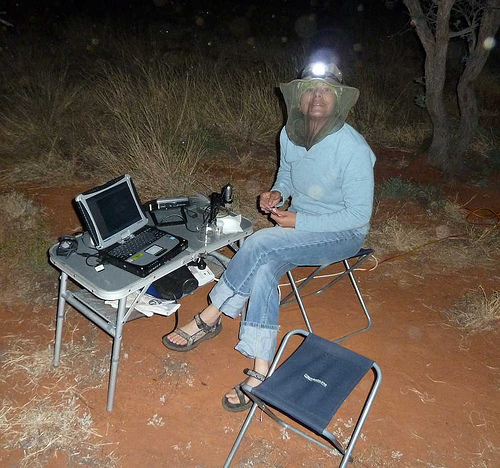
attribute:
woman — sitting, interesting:
[160, 47, 386, 418]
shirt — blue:
[250, 120, 384, 242]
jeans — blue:
[189, 217, 367, 353]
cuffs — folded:
[207, 272, 286, 356]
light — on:
[308, 62, 329, 79]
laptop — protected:
[69, 174, 182, 276]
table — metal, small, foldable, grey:
[45, 189, 254, 409]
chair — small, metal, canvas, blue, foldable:
[278, 232, 394, 345]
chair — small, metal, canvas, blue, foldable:
[225, 322, 405, 467]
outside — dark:
[0, 3, 499, 467]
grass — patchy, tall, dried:
[3, 34, 417, 186]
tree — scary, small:
[399, 5, 497, 177]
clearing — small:
[10, 118, 499, 468]